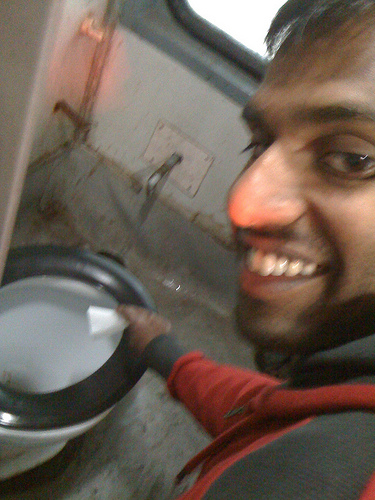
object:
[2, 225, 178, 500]
toilet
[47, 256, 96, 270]
seat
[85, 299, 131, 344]
cloth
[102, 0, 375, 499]
man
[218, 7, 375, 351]
face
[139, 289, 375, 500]
jacket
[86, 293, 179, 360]
hand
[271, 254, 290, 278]
tooth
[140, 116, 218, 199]
plate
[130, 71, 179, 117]
wall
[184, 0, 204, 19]
corner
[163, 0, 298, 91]
window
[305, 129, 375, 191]
eye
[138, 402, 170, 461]
floor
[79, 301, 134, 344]
tissue paper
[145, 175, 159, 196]
tap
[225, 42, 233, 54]
rim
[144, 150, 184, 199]
pipe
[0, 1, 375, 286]
background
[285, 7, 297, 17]
hair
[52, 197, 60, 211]
rust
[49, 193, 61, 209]
corner